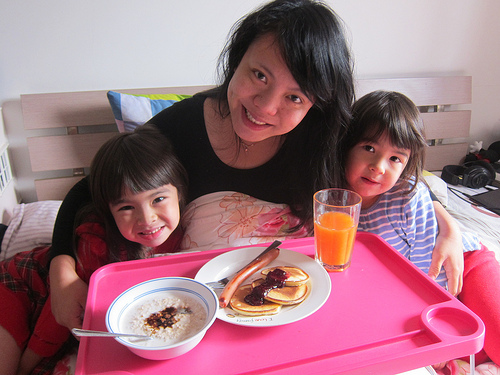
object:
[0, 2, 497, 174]
wall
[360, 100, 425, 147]
bangs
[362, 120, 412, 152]
forehead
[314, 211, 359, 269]
orange juice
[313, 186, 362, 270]
glass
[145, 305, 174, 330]
topping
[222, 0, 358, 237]
hair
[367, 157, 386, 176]
nose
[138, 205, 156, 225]
nose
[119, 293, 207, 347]
oatmeal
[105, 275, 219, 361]
bowl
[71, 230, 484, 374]
pink tray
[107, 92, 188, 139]
pillow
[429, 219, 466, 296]
hand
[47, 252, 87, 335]
hand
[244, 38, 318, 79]
forehead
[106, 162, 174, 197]
forehead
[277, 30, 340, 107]
bang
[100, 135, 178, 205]
bang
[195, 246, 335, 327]
plate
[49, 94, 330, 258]
shirt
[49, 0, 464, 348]
woman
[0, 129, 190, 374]
girl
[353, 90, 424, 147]
hair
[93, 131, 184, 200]
hair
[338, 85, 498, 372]
girl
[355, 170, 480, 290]
striped shirt